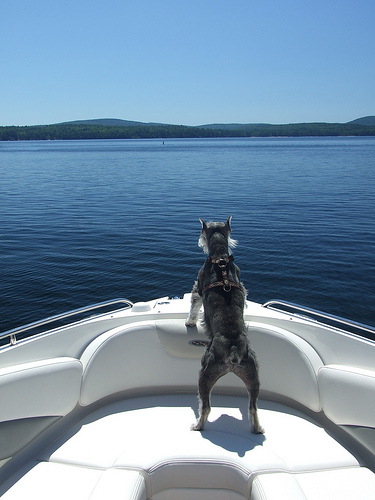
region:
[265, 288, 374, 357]
Silver railing on boat.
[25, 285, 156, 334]
Silver railing on boat.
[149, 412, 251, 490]
Cushions on boat are white.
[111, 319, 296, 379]
Seat back cushions are white in color.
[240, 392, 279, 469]
Dog has gray foot.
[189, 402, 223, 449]
Dog has gray foot.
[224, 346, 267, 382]
Dog has gray tail.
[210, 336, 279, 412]
Dog has gray butt.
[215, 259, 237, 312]
Brown harness on dog.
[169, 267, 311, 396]
Dog is standing on back of boat.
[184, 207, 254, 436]
dog standing on boat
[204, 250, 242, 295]
harness on dog body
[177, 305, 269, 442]
dog standing on back legs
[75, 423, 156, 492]
white cushions on seat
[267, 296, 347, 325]
metal rail on boat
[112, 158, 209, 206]
surface of calm water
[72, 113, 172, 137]
mountain top on horizon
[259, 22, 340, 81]
blue of daytime sky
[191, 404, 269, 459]
dog shadow on cushion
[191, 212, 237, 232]
pointy ears on dog head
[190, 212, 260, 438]
the dog perched on the boat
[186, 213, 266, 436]
the dog standing on the boat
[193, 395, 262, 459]
the shadow of the dog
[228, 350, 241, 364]
the dog's small tail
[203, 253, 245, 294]
the dog's harness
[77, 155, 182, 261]
the calm blue waters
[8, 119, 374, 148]
the trees in the distance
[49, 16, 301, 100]
the clear blue sky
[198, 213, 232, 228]
the dog's ears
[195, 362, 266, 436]
the dog's back legs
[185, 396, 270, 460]
A dog's shadow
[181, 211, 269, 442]
A dog standing on his hind feet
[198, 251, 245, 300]
A dog harness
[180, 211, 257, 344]
A dog wearing a harness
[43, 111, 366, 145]
Scenic mountains and trees in the background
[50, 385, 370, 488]
Boat cushions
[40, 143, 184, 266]
Shades of blue water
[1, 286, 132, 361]
Boat railing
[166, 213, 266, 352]
Dog leaning on boat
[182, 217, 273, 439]
Dog with clipped tail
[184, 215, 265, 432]
a grey dog on the bow of the boat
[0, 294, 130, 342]
stainless safety hand rails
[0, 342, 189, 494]
bow cushions in the boat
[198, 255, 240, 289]
a brown chest harness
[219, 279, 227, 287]
dog collar leash link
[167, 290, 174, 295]
the boats bow running light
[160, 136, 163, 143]
a buoy in the distance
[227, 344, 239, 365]
the dogs stubby tail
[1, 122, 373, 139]
trees an bushes on the shoreline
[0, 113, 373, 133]
hills beyond the trees